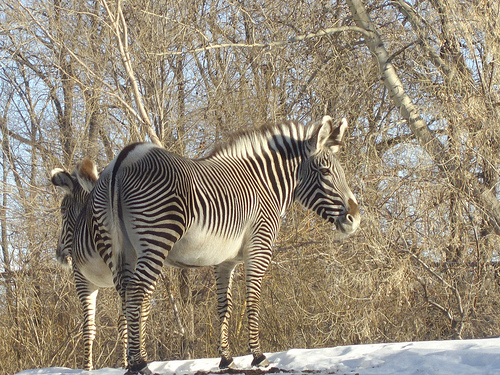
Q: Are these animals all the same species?
A: Yes, all the animals are zebras.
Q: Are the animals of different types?
A: No, all the animals are zebras.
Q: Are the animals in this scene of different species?
A: No, all the animals are zebras.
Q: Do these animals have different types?
A: No, all the animals are zebras.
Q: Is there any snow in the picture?
A: Yes, there is snow.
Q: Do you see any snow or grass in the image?
A: Yes, there is snow.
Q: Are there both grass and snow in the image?
A: No, there is snow but no grass.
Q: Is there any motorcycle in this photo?
A: No, there are no motorcycles.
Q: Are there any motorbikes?
A: No, there are no motorbikes.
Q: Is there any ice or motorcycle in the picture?
A: No, there are no motorcycles or ice.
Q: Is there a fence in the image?
A: No, there are no fences.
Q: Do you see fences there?
A: No, there are no fences.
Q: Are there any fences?
A: No, there are no fences.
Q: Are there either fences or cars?
A: No, there are no fences or cars.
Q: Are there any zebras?
A: Yes, there is a zebra.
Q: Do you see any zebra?
A: Yes, there is a zebra.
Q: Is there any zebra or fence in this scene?
A: Yes, there is a zebra.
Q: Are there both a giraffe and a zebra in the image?
A: No, there is a zebra but no giraffes.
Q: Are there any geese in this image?
A: No, there are no geese.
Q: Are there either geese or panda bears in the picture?
A: No, there are no geese or panda bears.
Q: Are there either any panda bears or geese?
A: No, there are no geese or panda bears.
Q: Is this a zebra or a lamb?
A: This is a zebra.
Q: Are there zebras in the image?
A: Yes, there are zebras.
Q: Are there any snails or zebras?
A: Yes, there are zebras.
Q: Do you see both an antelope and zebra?
A: No, there are zebras but no antelopes.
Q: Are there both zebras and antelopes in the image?
A: No, there are zebras but no antelopes.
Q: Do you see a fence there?
A: No, there are no fences.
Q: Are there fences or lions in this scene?
A: No, there are no fences or lions.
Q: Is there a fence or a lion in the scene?
A: No, there are no fences or lions.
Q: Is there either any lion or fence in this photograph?
A: No, there are no fences or lions.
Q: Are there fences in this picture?
A: No, there are no fences.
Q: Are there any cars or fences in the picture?
A: No, there are no fences or cars.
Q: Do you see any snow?
A: Yes, there is snow.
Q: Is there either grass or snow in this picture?
A: Yes, there is snow.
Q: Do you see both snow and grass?
A: No, there is snow but no grass.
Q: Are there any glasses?
A: No, there are no glasses.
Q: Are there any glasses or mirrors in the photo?
A: No, there are no glasses or mirrors.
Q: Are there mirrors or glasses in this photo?
A: No, there are no glasses or mirrors.